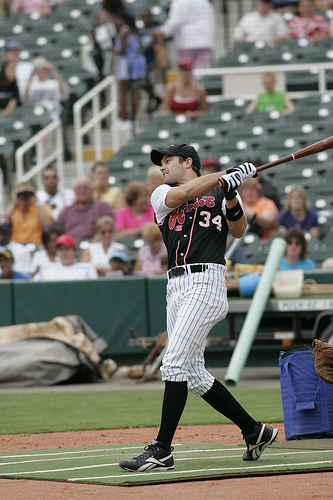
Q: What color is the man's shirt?
A: Black.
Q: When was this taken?
A: Daytime.